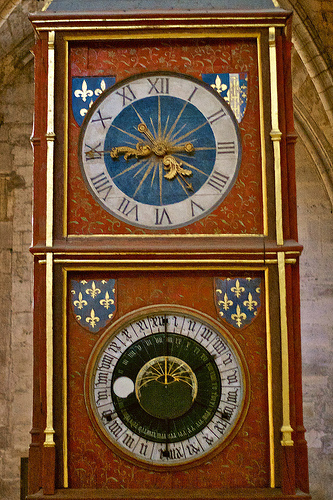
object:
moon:
[111, 374, 134, 397]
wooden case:
[24, 9, 311, 499]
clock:
[77, 71, 241, 236]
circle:
[113, 377, 133, 398]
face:
[84, 303, 244, 460]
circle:
[103, 95, 214, 208]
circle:
[109, 332, 222, 442]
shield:
[70, 69, 120, 126]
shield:
[197, 68, 253, 116]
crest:
[215, 69, 254, 109]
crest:
[71, 74, 114, 125]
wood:
[35, 10, 286, 70]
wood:
[34, 231, 298, 278]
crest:
[214, 272, 262, 331]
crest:
[68, 274, 118, 332]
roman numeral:
[185, 442, 199, 456]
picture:
[135, 354, 199, 417]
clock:
[79, 299, 252, 475]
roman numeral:
[114, 75, 151, 109]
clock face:
[55, 37, 268, 237]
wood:
[265, 62, 325, 151]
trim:
[44, 33, 281, 239]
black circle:
[110, 331, 218, 439]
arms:
[72, 76, 104, 109]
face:
[89, 75, 251, 235]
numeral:
[207, 101, 231, 139]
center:
[114, 339, 194, 426]